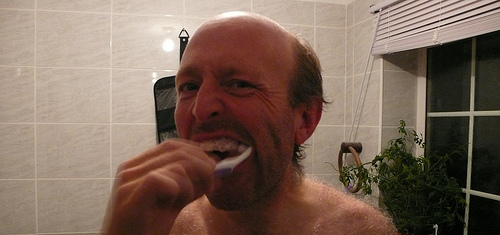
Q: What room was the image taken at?
A: It was taken at the bathroom.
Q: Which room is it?
A: It is a bathroom.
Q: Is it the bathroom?
A: Yes, it is the bathroom.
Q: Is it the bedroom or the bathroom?
A: It is the bathroom.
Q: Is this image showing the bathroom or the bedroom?
A: It is showing the bathroom.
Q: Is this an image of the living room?
A: No, the picture is showing the bathroom.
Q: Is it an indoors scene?
A: Yes, it is indoors.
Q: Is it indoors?
A: Yes, it is indoors.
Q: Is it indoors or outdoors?
A: It is indoors.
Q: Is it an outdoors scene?
A: No, it is indoors.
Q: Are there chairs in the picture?
A: No, there are no chairs.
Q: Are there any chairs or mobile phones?
A: No, there are no chairs or mobile phones.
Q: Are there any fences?
A: No, there are no fences.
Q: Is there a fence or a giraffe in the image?
A: No, there are no fences or giraffes.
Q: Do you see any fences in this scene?
A: No, there are no fences.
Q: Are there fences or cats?
A: No, there are no fences or cats.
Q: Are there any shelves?
A: No, there are no shelves.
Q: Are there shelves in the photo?
A: No, there are no shelves.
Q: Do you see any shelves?
A: No, there are no shelves.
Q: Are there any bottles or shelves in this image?
A: No, there are no shelves or bottles.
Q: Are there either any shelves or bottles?
A: No, there are no shelves or bottles.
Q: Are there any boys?
A: No, there are no boys.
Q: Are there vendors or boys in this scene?
A: No, there are no boys or vendors.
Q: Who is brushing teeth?
A: The man is brushing teeth.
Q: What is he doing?
A: The man is brushing teeth.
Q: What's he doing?
A: The man is brushing teeth.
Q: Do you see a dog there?
A: No, there are no dogs.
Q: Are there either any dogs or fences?
A: No, there are no dogs or fences.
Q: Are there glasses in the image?
A: No, there are no glasses.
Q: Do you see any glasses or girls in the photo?
A: No, there are no glasses or girls.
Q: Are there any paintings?
A: No, there are no paintings.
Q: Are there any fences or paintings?
A: No, there are no paintings or fences.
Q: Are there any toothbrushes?
A: Yes, there is a toothbrush.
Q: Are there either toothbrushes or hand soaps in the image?
A: Yes, there is a toothbrush.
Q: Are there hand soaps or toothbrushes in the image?
A: Yes, there is a toothbrush.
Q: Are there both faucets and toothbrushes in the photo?
A: No, there is a toothbrush but no faucets.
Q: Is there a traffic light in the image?
A: No, there are no traffic lights.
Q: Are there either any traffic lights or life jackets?
A: No, there are no traffic lights or life jackets.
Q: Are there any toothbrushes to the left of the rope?
A: Yes, there is a toothbrush to the left of the rope.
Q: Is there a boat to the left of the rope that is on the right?
A: No, there is a toothbrush to the left of the rope.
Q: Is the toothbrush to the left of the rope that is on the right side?
A: Yes, the toothbrush is to the left of the rope.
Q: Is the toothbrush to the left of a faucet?
A: No, the toothbrush is to the left of the rope.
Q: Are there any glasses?
A: No, there are no glasses.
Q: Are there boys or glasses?
A: No, there are no glasses or boys.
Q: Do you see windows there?
A: Yes, there is a window.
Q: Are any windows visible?
A: Yes, there is a window.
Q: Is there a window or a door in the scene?
A: Yes, there is a window.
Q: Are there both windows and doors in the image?
A: No, there is a window but no doors.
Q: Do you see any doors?
A: No, there are no doors.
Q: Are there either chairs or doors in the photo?
A: No, there are no doors or chairs.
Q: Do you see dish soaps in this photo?
A: No, there are no dish soaps.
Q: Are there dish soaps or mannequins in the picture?
A: No, there are no dish soaps or mannequins.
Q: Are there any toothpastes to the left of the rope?
A: Yes, there is a toothpaste to the left of the rope.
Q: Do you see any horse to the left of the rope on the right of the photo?
A: No, there is a toothpaste to the left of the rope.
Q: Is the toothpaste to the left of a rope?
A: Yes, the toothpaste is to the left of a rope.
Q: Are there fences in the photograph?
A: No, there are no fences.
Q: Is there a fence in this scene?
A: No, there are no fences.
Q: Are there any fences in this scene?
A: No, there are no fences.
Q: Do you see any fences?
A: No, there are no fences.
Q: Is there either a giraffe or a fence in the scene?
A: No, there are no fences or giraffes.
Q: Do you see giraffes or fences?
A: No, there are no fences or giraffes.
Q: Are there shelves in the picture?
A: No, there are no shelves.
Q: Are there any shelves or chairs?
A: No, there are no shelves or chairs.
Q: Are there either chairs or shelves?
A: No, there are no shelves or chairs.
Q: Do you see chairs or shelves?
A: No, there are no shelves or chairs.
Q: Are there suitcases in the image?
A: No, there are no suitcases.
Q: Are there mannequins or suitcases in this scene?
A: No, there are no suitcases or mannequins.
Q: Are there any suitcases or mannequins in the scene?
A: No, there are no suitcases or mannequins.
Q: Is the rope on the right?
A: Yes, the rope is on the right of the image.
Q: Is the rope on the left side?
A: No, the rope is on the right of the image.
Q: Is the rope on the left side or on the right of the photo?
A: The rope is on the right of the image.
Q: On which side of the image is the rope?
A: The rope is on the right of the image.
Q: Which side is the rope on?
A: The rope is on the right of the image.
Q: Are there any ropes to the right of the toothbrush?
A: Yes, there is a rope to the right of the toothbrush.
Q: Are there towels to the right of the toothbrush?
A: No, there is a rope to the right of the toothbrush.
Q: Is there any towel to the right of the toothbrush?
A: No, there is a rope to the right of the toothbrush.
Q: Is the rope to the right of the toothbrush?
A: Yes, the rope is to the right of the toothbrush.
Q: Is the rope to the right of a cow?
A: No, the rope is to the right of the toothbrush.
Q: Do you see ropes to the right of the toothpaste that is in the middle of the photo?
A: Yes, there is a rope to the right of the toothpaste.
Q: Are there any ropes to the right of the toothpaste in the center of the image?
A: Yes, there is a rope to the right of the toothpaste.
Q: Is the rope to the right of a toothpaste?
A: Yes, the rope is to the right of a toothpaste.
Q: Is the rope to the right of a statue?
A: No, the rope is to the right of a toothpaste.